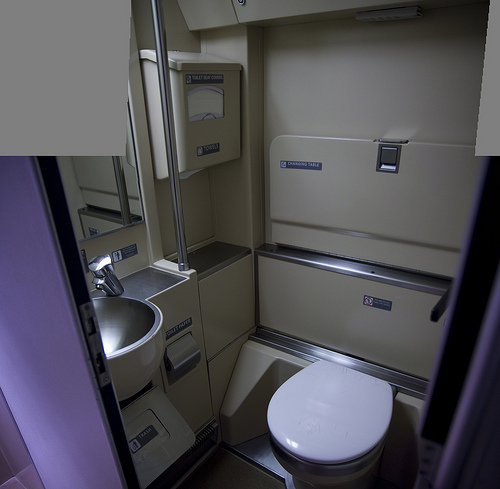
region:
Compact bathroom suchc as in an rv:
[6, 4, 493, 487]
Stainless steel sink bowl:
[67, 258, 172, 391]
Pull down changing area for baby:
[236, 111, 498, 284]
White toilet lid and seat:
[265, 348, 397, 463]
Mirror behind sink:
[30, 3, 143, 248]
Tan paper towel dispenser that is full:
[138, 28, 260, 195]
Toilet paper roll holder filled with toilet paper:
[158, 321, 215, 372]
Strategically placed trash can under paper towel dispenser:
[172, 221, 267, 335]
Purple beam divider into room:
[0, 140, 149, 485]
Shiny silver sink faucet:
[86, 250, 128, 299]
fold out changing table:
[251, 116, 493, 303]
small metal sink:
[50, 267, 193, 373]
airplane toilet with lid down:
[244, 338, 419, 473]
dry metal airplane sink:
[44, 250, 171, 372]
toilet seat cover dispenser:
[101, 31, 243, 173]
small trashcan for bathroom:
[171, 221, 258, 283]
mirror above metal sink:
[16, 90, 182, 257]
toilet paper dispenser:
[156, 313, 211, 389]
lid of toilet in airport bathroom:
[254, 323, 396, 460]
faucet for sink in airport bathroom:
[74, 248, 120, 285]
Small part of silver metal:
[371, 132, 400, 173]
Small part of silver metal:
[252, 232, 461, 306]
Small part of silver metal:
[163, 228, 257, 283]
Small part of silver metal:
[165, 334, 213, 374]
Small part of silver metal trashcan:
[113, 404, 180, 486]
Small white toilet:
[228, 343, 395, 479]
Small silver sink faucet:
[81, 250, 132, 308]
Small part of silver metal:
[220, 244, 247, 264]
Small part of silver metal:
[295, 459, 318, 477]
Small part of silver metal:
[324, 460, 361, 476]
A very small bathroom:
[67, 120, 472, 487]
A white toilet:
[261, 344, 405, 464]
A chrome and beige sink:
[87, 250, 173, 370]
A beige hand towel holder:
[141, 43, 248, 187]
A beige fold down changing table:
[271, 125, 499, 235]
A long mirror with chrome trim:
[68, 166, 145, 229]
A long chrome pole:
[141, 8, 207, 290]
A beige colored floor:
[200, 454, 254, 480]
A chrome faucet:
[86, 250, 129, 292]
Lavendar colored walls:
[435, 172, 498, 487]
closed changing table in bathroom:
[267, 133, 483, 280]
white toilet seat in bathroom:
[263, 357, 392, 462]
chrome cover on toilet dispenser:
[160, 329, 205, 383]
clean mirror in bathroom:
[51, 85, 146, 245]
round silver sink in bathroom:
[90, 292, 166, 402]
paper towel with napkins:
[132, 47, 241, 181]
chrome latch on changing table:
[379, 143, 399, 170]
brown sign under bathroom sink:
[125, 427, 164, 453]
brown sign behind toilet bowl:
[360, 293, 390, 309]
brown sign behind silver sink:
[107, 244, 134, 263]